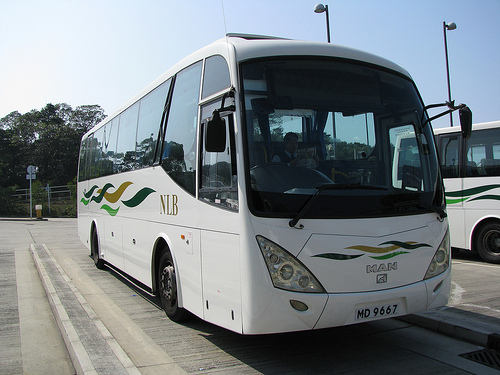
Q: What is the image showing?
A: It is showing a street.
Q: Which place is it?
A: It is a street.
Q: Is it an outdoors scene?
A: Yes, it is outdoors.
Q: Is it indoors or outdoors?
A: It is outdoors.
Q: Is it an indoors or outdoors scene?
A: It is outdoors.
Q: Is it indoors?
A: No, it is outdoors.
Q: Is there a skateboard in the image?
A: No, there are no skateboards.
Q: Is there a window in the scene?
A: Yes, there is a window.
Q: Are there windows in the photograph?
A: Yes, there is a window.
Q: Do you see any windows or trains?
A: Yes, there is a window.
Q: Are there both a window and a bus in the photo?
A: Yes, there are both a window and a bus.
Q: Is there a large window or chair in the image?
A: Yes, there is a large window.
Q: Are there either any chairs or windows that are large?
A: Yes, the window is large.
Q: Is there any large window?
A: Yes, there is a large window.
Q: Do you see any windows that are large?
A: Yes, there is a window that is large.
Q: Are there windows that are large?
A: Yes, there is a window that is large.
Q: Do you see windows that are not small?
A: Yes, there is a large window.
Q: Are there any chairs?
A: No, there are no chairs.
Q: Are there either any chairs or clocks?
A: No, there are no chairs or clocks.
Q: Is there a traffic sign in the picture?
A: Yes, there is a traffic sign.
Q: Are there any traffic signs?
A: Yes, there is a traffic sign.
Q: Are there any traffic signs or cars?
A: Yes, there is a traffic sign.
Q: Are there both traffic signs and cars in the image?
A: No, there is a traffic sign but no cars.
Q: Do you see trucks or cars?
A: No, there are no cars or trucks.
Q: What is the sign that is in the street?
A: The sign is a traffic sign.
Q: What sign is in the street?
A: The sign is a traffic sign.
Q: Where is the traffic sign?
A: The traffic sign is in the street.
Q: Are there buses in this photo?
A: Yes, there is a bus.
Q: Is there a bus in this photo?
A: Yes, there is a bus.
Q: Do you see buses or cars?
A: Yes, there is a bus.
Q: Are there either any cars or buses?
A: Yes, there is a bus.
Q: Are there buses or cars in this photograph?
A: Yes, there is a bus.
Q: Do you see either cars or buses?
A: Yes, there is a bus.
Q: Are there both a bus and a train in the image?
A: No, there is a bus but no trains.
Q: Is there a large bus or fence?
A: Yes, there is a large bus.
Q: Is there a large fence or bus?
A: Yes, there is a large bus.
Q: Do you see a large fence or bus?
A: Yes, there is a large bus.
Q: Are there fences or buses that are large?
A: Yes, the bus is large.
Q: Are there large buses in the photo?
A: Yes, there is a large bus.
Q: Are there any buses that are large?
A: Yes, there is a bus that is large.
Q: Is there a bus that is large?
A: Yes, there is a bus that is large.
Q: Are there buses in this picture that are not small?
A: Yes, there is a large bus.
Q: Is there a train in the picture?
A: No, there are no trains.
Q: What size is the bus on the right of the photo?
A: The bus is large.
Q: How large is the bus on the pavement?
A: The bus is large.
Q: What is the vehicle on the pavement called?
A: The vehicle is a bus.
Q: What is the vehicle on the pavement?
A: The vehicle is a bus.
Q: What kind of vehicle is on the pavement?
A: The vehicle is a bus.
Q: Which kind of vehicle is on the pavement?
A: The vehicle is a bus.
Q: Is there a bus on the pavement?
A: Yes, there is a bus on the pavement.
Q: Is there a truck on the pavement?
A: No, there is a bus on the pavement.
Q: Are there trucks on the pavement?
A: No, there is a bus on the pavement.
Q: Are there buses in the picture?
A: Yes, there is a bus.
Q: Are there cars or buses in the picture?
A: Yes, there is a bus.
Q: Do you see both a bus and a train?
A: No, there is a bus but no trains.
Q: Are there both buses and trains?
A: No, there is a bus but no trains.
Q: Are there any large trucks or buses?
A: Yes, there is a large bus.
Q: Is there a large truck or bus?
A: Yes, there is a large bus.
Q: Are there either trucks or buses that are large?
A: Yes, the bus is large.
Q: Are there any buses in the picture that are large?
A: Yes, there is a large bus.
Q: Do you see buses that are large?
A: Yes, there is a bus that is large.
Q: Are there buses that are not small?
A: Yes, there is a large bus.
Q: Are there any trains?
A: No, there are no trains.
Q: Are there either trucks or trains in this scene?
A: No, there are no trains or trucks.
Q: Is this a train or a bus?
A: This is a bus.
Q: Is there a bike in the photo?
A: No, there are no bikes.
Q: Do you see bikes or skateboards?
A: No, there are no bikes or skateboards.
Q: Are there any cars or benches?
A: No, there are no cars or benches.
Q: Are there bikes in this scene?
A: No, there are no bikes.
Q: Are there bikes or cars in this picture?
A: No, there are no bikes or cars.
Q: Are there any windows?
A: Yes, there is a window.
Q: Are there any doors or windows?
A: Yes, there is a window.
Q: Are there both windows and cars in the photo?
A: No, there is a window but no cars.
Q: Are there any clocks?
A: No, there are no clocks.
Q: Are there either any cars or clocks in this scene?
A: No, there are no clocks or cars.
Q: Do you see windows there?
A: Yes, there are windows.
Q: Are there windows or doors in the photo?
A: Yes, there are windows.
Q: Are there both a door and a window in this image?
A: Yes, there are both a window and a door.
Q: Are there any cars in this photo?
A: No, there are no cars.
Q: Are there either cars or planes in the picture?
A: No, there are no cars or planes.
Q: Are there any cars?
A: No, there are no cars.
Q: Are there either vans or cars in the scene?
A: No, there are no cars or vans.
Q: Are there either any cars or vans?
A: No, there are no cars or vans.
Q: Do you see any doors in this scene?
A: Yes, there is a door.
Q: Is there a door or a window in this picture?
A: Yes, there is a door.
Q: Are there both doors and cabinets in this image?
A: No, there is a door but no cabinets.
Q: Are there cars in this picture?
A: No, there are no cars.